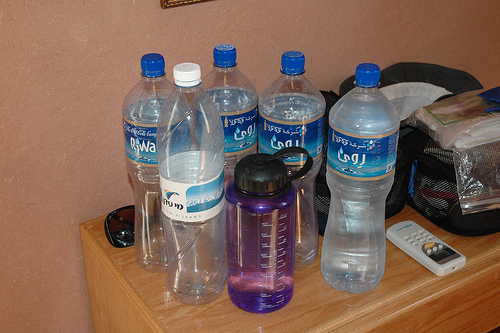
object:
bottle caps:
[140, 40, 382, 91]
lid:
[230, 150, 290, 194]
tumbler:
[221, 187, 305, 315]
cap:
[172, 61, 202, 83]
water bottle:
[156, 62, 224, 307]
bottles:
[121, 44, 401, 313]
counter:
[77, 231, 146, 332]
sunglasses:
[101, 204, 148, 252]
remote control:
[383, 219, 465, 278]